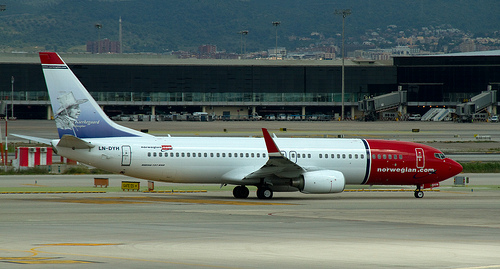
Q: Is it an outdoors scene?
A: Yes, it is outdoors.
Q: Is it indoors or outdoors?
A: It is outdoors.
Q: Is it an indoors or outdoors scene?
A: It is outdoors.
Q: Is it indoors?
A: No, it is outdoors.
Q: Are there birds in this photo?
A: No, there are no birds.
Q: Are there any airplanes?
A: Yes, there is an airplane.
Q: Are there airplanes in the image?
A: Yes, there is an airplane.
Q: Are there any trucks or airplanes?
A: Yes, there is an airplane.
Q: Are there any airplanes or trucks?
A: Yes, there is an airplane.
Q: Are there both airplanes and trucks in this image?
A: No, there is an airplane but no trucks.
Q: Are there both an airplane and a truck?
A: No, there is an airplane but no trucks.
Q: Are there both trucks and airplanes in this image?
A: No, there is an airplane but no trucks.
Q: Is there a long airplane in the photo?
A: Yes, there is a long airplane.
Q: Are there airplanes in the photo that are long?
A: Yes, there is an airplane that is long.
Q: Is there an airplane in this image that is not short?
A: Yes, there is a long airplane.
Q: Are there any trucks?
A: No, there are no trucks.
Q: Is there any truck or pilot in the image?
A: No, there are no trucks or pilots.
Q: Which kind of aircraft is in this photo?
A: The aircraft is an airplane.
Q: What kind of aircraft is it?
A: The aircraft is an airplane.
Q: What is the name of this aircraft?
A: This is an airplane.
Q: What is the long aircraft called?
A: The aircraft is an airplane.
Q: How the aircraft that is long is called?
A: The aircraft is an airplane.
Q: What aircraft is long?
A: The aircraft is an airplane.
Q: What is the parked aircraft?
A: The aircraft is an airplane.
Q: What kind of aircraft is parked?
A: The aircraft is an airplane.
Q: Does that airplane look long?
A: Yes, the airplane is long.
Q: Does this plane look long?
A: Yes, the plane is long.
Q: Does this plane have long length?
A: Yes, the plane is long.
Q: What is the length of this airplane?
A: The airplane is long.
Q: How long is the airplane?
A: The airplane is long.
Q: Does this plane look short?
A: No, the plane is long.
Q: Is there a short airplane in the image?
A: No, there is an airplane but it is long.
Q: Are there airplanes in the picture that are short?
A: No, there is an airplane but it is long.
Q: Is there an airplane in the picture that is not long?
A: No, there is an airplane but it is long.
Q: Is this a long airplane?
A: Yes, this is a long airplane.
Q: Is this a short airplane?
A: No, this is a long airplane.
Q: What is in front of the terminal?
A: The plane is in front of the terminal.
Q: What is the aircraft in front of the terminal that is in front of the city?
A: The aircraft is an airplane.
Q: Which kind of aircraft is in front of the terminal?
A: The aircraft is an airplane.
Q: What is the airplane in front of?
A: The airplane is in front of the terminal.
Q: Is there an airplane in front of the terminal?
A: Yes, there is an airplane in front of the terminal.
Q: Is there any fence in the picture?
A: No, there are no fences.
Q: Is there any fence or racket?
A: No, there are no fences or rackets.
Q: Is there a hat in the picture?
A: Yes, there is a hat.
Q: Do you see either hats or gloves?
A: Yes, there is a hat.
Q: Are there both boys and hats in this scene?
A: No, there is a hat but no boys.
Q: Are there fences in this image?
A: No, there are no fences.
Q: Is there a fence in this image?
A: No, there are no fences.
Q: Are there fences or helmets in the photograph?
A: No, there are no fences or helmets.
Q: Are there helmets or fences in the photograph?
A: No, there are no fences or helmets.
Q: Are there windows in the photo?
A: Yes, there are windows.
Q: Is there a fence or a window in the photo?
A: Yes, there are windows.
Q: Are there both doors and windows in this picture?
A: Yes, there are both windows and a door.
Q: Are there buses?
A: No, there are no buses.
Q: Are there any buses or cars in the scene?
A: No, there are no buses or cars.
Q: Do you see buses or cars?
A: No, there are no buses or cars.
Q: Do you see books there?
A: No, there are no books.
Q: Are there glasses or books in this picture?
A: No, there are no books or glasses.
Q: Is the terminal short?
A: Yes, the terminal is short.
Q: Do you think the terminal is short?
A: Yes, the terminal is short.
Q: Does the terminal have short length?
A: Yes, the terminal is short.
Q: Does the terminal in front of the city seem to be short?
A: Yes, the terminal is short.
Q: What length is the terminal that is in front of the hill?
A: The terminal is short.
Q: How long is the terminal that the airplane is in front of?
A: The terminal is short.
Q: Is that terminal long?
A: No, the terminal is short.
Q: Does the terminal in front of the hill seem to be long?
A: No, the terminal is short.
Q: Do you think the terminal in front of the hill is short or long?
A: The terminal is short.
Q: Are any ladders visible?
A: No, there are no ladders.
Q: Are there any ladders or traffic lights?
A: No, there are no ladders or traffic lights.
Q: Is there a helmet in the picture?
A: No, there are no helmets.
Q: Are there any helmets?
A: No, there are no helmets.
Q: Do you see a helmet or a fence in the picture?
A: No, there are no helmets or fences.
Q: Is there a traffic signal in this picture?
A: No, there are no traffic lights.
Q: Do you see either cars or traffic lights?
A: No, there are no traffic lights or cars.